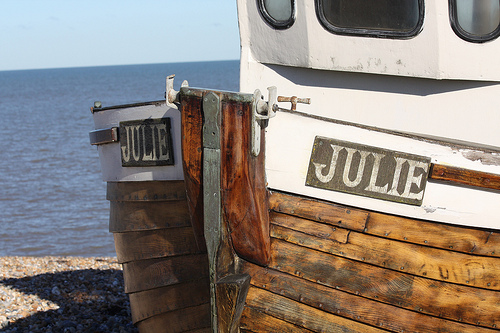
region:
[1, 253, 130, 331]
Rocky land next to the water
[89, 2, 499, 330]
Boat on a rocky beach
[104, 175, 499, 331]
Wooden hull on a boat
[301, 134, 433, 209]
Wooden board with white letters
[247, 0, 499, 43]
Glass windows on a boat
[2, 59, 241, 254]
Water behind a boat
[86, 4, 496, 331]
white and brown boat is beached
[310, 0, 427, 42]
wide rectangle window on cabin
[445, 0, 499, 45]
thin oblong window on cabin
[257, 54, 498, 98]
shadow of windowsill on boat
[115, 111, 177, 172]
brown sign with white letters in shadow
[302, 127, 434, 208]
brown sign with Julie in white letters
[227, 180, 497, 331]
brown wood slats of boat bottom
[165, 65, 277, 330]
black metal tow bar on front of boat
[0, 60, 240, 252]
calm blue water behind boat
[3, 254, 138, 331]
ground densely covered in pebbles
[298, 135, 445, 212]
brown and white sign on boat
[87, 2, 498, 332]
brown and white boat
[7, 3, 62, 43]
white clouds in blue sky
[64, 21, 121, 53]
white clouds in blue sky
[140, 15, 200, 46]
white clouds in blue sky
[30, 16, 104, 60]
white clouds in blue sky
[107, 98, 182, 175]
sign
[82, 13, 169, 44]
white clouds in blue sky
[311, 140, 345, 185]
white letter on boat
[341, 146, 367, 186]
white letter on boat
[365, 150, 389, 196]
white letter on boat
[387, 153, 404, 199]
white letter on boat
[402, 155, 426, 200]
white letter on boat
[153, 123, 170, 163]
white letter on boat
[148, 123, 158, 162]
white letter on boat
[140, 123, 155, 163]
white letter on boat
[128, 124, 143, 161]
white letter on boat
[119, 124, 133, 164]
white letter on boat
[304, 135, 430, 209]
the word JULIE on the sign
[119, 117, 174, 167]
the word JULIE on the sign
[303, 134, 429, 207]
the white letters on the sign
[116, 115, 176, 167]
the white letters on the sign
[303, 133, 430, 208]
the black sign with white letters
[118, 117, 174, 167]
the black sign with white letters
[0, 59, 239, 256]
the large body of water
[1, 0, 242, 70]
the blue sky above the water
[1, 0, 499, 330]
the boat on the shore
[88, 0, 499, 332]
the windows on the boat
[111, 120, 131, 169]
White letter on black sign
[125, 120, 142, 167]
White letter on black sign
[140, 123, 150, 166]
White letter on black sign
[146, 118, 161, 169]
White letter on black sign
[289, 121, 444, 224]
a boat named Julie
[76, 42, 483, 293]
a boat next to the lake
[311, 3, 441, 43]
the window on the front of the boat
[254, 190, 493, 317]
A wooden section on the front of the boat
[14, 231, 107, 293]
a section of beach the lake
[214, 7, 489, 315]
The front end of a boat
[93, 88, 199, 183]
name on the boat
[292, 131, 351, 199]
letter on the boat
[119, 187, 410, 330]
bottom part of the boat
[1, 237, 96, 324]
shadow on the ground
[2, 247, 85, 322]
rocks on the ground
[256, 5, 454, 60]
windows on the boat